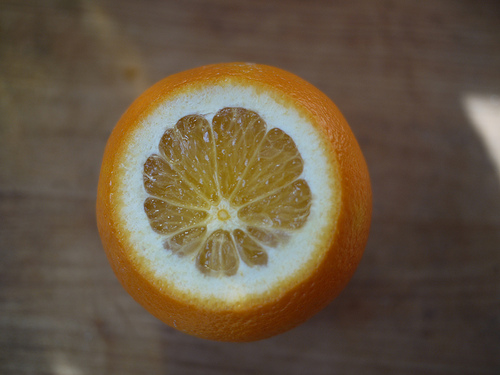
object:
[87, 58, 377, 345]
orange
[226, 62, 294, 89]
skin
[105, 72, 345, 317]
top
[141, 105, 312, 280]
inside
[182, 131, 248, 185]
light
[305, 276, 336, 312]
shadow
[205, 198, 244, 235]
inner core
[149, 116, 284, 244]
surface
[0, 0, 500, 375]
table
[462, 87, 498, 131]
side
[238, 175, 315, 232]
slice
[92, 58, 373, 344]
rind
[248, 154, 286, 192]
pulp